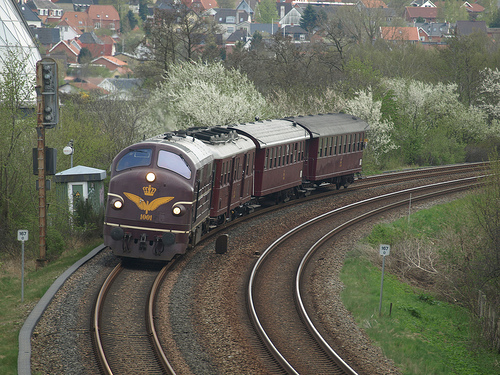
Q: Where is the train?
A: Tracks.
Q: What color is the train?
A: Brown.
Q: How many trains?
A: 1.